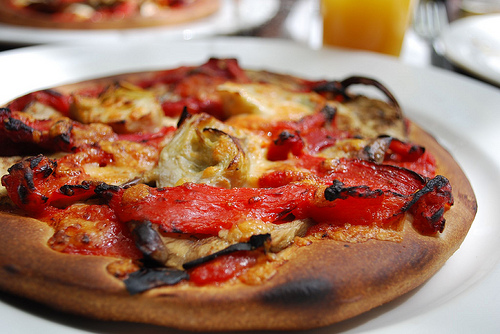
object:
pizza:
[3, 59, 478, 332]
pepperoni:
[118, 177, 263, 232]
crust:
[23, 262, 113, 309]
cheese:
[90, 156, 154, 186]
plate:
[430, 13, 499, 83]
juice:
[325, 0, 409, 46]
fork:
[410, 1, 447, 68]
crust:
[258, 273, 350, 320]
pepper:
[310, 161, 444, 227]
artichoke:
[157, 112, 252, 188]